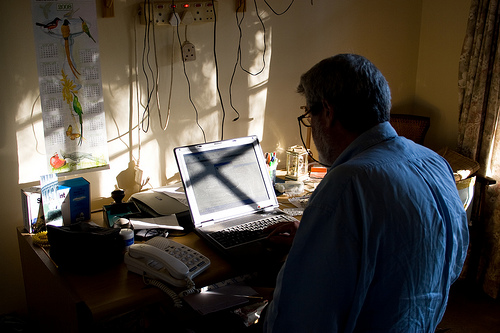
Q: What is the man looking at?
A: Computer.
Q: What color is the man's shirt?
A: Blue.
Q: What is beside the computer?
A: A phone.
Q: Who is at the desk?
A: A man.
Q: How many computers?
A: 1.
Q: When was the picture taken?
A: Daytime.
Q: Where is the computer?
A: On the desk.